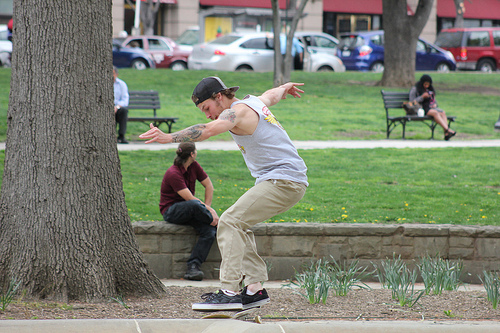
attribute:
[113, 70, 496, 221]
park — green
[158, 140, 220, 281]
person — turned away, sitting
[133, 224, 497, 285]
wall — stone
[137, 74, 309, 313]
skater — extended, skating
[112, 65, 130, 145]
man — sitting, light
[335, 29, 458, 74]
car — parked, blue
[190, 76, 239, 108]
cap — backwards, black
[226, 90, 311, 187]
tank — grey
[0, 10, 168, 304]
trunk — large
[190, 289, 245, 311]
shoe — black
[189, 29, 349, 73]
vehicle — silver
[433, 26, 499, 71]
suv — red, parked